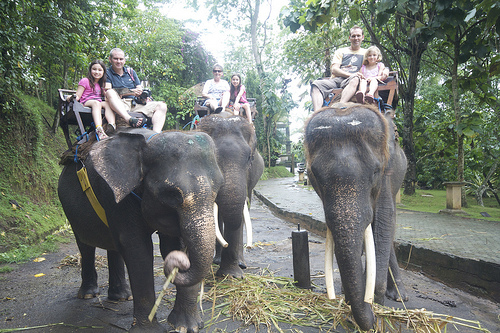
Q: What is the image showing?
A: It is showing a path.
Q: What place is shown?
A: It is a path.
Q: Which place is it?
A: It is a path.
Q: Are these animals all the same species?
A: Yes, all the animals are elephants.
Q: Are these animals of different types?
A: No, all the animals are elephants.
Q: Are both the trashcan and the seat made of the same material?
A: No, the trashcan is made of concrete and the seat is made of wood.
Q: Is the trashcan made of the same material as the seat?
A: No, the trashcan is made of concrete and the seat is made of wood.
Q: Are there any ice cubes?
A: No, there are no ice cubes.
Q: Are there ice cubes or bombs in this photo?
A: No, there are no ice cubes or bombs.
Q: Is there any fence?
A: No, there are no fences.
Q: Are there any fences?
A: No, there are no fences.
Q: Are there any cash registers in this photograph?
A: No, there are no cash registers.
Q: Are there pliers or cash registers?
A: No, there are no cash registers or pliers.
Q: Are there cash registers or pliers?
A: No, there are no cash registers or pliers.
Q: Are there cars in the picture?
A: No, there are no cars.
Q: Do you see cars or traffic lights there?
A: No, there are no cars or traffic lights.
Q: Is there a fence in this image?
A: No, there are no fences.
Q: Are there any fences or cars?
A: No, there are no fences or cars.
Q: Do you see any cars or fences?
A: No, there are no fences or cars.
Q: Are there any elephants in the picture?
A: Yes, there is an elephant.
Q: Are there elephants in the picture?
A: Yes, there is an elephant.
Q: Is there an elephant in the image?
A: Yes, there is an elephant.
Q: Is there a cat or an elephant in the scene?
A: Yes, there is an elephant.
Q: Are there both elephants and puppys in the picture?
A: No, there is an elephant but no puppys.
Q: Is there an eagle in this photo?
A: No, there are no eagles.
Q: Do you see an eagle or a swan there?
A: No, there are no eagles or swans.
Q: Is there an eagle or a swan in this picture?
A: No, there are no eagles or swans.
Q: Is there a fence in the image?
A: No, there are no fences.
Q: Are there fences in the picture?
A: No, there are no fences.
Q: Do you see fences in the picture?
A: No, there are no fences.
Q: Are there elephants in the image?
A: Yes, there is an elephant.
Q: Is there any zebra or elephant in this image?
A: Yes, there is an elephant.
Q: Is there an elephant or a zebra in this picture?
A: Yes, there is an elephant.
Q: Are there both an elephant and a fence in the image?
A: No, there is an elephant but no fences.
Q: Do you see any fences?
A: No, there are no fences.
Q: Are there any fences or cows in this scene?
A: No, there are no fences or cows.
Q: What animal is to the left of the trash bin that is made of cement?
A: The animal is an elephant.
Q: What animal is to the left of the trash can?
A: The animal is an elephant.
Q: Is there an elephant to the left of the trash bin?
A: Yes, there is an elephant to the left of the trash bin.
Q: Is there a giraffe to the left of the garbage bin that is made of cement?
A: No, there is an elephant to the left of the garbage can.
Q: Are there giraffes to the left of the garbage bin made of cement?
A: No, there is an elephant to the left of the garbage can.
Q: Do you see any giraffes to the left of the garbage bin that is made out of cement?
A: No, there is an elephant to the left of the garbage can.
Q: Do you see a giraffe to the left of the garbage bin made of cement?
A: No, there is an elephant to the left of the garbage can.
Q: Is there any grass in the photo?
A: Yes, there is grass.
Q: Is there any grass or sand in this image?
A: Yes, there is grass.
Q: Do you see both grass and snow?
A: No, there is grass but no snow.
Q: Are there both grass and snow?
A: No, there is grass but no snow.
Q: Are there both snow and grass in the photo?
A: No, there is grass but no snow.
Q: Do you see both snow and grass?
A: No, there is grass but no snow.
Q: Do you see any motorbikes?
A: No, there are no motorbikes.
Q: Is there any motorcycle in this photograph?
A: No, there are no motorcycles.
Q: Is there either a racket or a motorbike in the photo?
A: No, there are no motorcycles or rackets.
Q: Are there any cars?
A: No, there are no cars.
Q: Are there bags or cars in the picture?
A: No, there are no cars or bags.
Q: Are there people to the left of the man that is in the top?
A: Yes, there are people to the left of the man.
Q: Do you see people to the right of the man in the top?
A: No, the people are to the left of the man.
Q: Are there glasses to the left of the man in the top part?
A: No, there are people to the left of the man.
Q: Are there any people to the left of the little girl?
A: Yes, there are people to the left of the girl.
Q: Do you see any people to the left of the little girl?
A: Yes, there are people to the left of the girl.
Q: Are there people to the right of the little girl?
A: No, the people are to the left of the girl.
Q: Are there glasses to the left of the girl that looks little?
A: No, there are people to the left of the girl.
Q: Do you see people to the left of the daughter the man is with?
A: Yes, there are people to the left of the daughter.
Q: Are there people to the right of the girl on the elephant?
A: Yes, there are people to the right of the girl.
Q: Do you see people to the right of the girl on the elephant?
A: Yes, there are people to the right of the girl.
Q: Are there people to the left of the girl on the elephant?
A: No, the people are to the right of the girl.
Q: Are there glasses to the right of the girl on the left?
A: No, there are people to the right of the girl.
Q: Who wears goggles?
A: The people wear goggles.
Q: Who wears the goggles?
A: The people wear goggles.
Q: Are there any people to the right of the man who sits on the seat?
A: Yes, there are people to the right of the man.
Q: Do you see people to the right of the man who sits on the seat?
A: Yes, there are people to the right of the man.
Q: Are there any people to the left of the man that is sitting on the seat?
A: No, the people are to the right of the man.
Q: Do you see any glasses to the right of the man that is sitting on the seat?
A: No, there are people to the right of the man.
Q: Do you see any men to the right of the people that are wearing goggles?
A: Yes, there is a man to the right of the people.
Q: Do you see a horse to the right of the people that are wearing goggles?
A: No, there is a man to the right of the people.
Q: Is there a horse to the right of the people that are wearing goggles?
A: No, there is a man to the right of the people.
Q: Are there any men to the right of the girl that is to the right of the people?
A: Yes, there is a man to the right of the girl.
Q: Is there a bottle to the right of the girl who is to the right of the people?
A: No, there is a man to the right of the girl.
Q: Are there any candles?
A: No, there are no candles.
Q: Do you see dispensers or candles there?
A: No, there are no candles or dispensers.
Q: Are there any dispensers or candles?
A: No, there are no candles or dispensers.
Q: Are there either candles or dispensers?
A: No, there are no candles or dispensers.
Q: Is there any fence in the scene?
A: No, there are no fences.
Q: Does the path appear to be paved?
A: Yes, the path is paved.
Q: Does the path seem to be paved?
A: Yes, the path is paved.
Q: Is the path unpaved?
A: No, the path is paved.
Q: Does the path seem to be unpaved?
A: No, the path is paved.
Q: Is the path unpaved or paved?
A: The path is paved.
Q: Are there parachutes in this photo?
A: No, there are no parachutes.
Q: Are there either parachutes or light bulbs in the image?
A: No, there are no parachutes or light bulbs.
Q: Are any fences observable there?
A: No, there are no fences.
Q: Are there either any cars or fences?
A: No, there are no fences or cars.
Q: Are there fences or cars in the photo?
A: No, there are no fences or cars.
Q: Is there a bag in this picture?
A: No, there are no bags.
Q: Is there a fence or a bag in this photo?
A: No, there are no bags or fences.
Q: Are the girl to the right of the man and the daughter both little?
A: Yes, both the girl and the daughter are little.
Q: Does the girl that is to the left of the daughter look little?
A: Yes, the girl is little.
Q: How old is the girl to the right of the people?
A: The girl is little.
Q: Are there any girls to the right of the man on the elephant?
A: Yes, there is a girl to the right of the man.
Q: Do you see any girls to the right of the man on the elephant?
A: Yes, there is a girl to the right of the man.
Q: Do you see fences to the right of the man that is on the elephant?
A: No, there is a girl to the right of the man.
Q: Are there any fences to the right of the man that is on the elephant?
A: No, there is a girl to the right of the man.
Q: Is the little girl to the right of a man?
A: Yes, the girl is to the right of a man.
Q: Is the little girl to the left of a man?
A: No, the girl is to the right of a man.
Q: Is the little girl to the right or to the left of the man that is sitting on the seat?
A: The girl is to the right of the man.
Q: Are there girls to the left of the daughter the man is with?
A: Yes, there is a girl to the left of the daughter.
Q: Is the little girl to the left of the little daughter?
A: Yes, the girl is to the left of the daughter.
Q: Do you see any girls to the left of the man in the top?
A: Yes, there is a girl to the left of the man.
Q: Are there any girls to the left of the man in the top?
A: Yes, there is a girl to the left of the man.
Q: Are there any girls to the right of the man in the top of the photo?
A: No, the girl is to the left of the man.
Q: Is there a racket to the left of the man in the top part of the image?
A: No, there is a girl to the left of the man.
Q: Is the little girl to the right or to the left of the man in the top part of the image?
A: The girl is to the left of the man.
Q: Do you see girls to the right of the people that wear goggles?
A: Yes, there is a girl to the right of the people.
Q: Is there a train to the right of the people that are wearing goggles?
A: No, there is a girl to the right of the people.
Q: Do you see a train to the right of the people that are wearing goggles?
A: No, there is a girl to the right of the people.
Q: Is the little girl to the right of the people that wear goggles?
A: Yes, the girl is to the right of the people.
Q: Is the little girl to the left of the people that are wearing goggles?
A: No, the girl is to the right of the people.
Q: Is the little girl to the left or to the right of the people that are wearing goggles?
A: The girl is to the right of the people.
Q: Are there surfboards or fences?
A: No, there are no fences or surfboards.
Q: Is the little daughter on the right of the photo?
A: Yes, the daughter is on the right of the image.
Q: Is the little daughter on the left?
A: No, the daughter is on the right of the image.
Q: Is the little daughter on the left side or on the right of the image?
A: The daughter is on the right of the image.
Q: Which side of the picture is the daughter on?
A: The daughter is on the right of the image.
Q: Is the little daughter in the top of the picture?
A: Yes, the daughter is in the top of the image.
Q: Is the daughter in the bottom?
A: No, the daughter is in the top of the image.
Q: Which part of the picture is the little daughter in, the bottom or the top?
A: The daughter is in the top of the image.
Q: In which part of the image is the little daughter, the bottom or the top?
A: The daughter is in the top of the image.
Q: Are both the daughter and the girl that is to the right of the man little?
A: Yes, both the daughter and the girl are little.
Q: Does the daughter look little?
A: Yes, the daughter is little.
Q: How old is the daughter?
A: The daughter is little.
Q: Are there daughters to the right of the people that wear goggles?
A: Yes, there is a daughter to the right of the people.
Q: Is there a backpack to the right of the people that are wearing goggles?
A: No, there is a daughter to the right of the people.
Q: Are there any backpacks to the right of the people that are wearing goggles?
A: No, there is a daughter to the right of the people.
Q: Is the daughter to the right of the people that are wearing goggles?
A: Yes, the daughter is to the right of the people.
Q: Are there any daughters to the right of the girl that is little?
A: Yes, there is a daughter to the right of the girl.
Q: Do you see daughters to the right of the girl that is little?
A: Yes, there is a daughter to the right of the girl.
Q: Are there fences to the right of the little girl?
A: No, there is a daughter to the right of the girl.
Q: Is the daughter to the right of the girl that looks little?
A: Yes, the daughter is to the right of the girl.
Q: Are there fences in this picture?
A: No, there are no fences.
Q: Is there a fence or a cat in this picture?
A: No, there are no fences or cats.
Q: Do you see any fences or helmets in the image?
A: No, there are no fences or helmets.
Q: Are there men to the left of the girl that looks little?
A: Yes, there is a man to the left of the girl.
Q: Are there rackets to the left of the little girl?
A: No, there is a man to the left of the girl.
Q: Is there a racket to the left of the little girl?
A: No, there is a man to the left of the girl.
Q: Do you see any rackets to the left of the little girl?
A: No, there is a man to the left of the girl.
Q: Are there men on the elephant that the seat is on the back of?
A: Yes, there is a man on the elephant.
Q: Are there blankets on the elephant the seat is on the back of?
A: No, there is a man on the elephant.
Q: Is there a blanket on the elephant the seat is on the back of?
A: No, there is a man on the elephant.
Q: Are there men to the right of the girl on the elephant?
A: Yes, there is a man to the right of the girl.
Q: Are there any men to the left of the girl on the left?
A: No, the man is to the right of the girl.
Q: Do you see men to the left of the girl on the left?
A: No, the man is to the right of the girl.